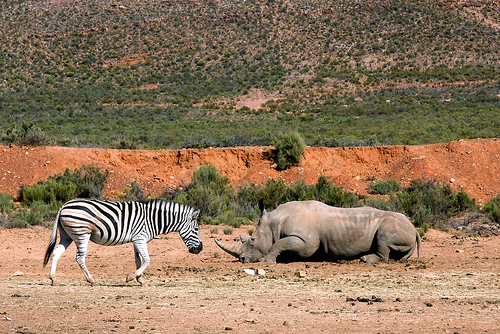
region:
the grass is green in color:
[209, 105, 259, 130]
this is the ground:
[331, 162, 350, 169]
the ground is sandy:
[342, 149, 378, 174]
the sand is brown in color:
[320, 156, 342, 168]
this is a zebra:
[42, 194, 214, 284]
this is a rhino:
[222, 197, 411, 268]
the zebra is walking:
[39, 183, 212, 290]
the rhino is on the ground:
[221, 203, 416, 270]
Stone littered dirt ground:
[167, 290, 286, 325]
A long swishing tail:
[38, 218, 61, 265]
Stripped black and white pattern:
[88, 197, 194, 239]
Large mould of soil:
[342, 152, 452, 171]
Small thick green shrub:
[263, 132, 315, 174]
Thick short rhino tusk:
[214, 235, 241, 255]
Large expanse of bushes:
[129, 22, 356, 84]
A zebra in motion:
[67, 190, 209, 266]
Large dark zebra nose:
[186, 245, 209, 254]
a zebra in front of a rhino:
[45, 192, 422, 281]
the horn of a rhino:
[212, 228, 241, 259]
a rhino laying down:
[213, 199, 424, 270]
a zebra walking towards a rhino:
[47, 193, 211, 289]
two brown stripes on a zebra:
[55, 213, 99, 233]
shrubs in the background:
[17, 167, 475, 225]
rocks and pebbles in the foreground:
[21, 286, 497, 332]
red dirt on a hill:
[2, 139, 498, 195]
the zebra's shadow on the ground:
[21, 270, 146, 293]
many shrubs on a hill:
[4, 2, 497, 108]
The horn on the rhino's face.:
[213, 239, 240, 256]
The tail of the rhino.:
[407, 223, 424, 261]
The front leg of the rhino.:
[257, 240, 306, 267]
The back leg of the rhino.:
[362, 245, 389, 264]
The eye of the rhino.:
[246, 234, 263, 244]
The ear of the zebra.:
[192, 208, 198, 219]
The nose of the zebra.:
[195, 239, 203, 246]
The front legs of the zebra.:
[130, 237, 151, 287]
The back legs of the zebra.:
[50, 230, 95, 282]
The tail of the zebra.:
[40, 205, 62, 264]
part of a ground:
[196, 293, 223, 320]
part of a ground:
[240, 293, 268, 318]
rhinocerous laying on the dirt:
[222, 200, 419, 265]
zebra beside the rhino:
[40, 194, 203, 289]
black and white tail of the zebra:
[35, 208, 60, 268]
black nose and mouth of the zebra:
[190, 240, 202, 252]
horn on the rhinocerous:
[213, 237, 238, 254]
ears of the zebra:
[190, 202, 202, 221]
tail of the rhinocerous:
[414, 225, 426, 257]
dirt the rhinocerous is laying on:
[3, 223, 498, 329]